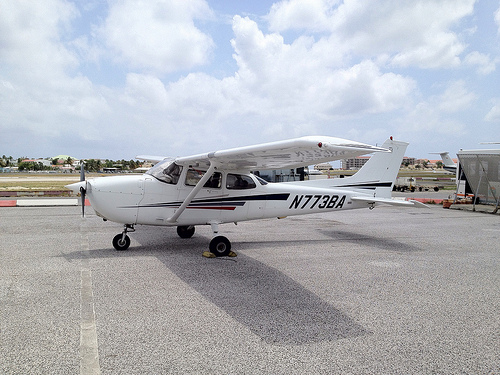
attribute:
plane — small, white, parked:
[62, 131, 432, 256]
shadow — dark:
[60, 223, 428, 344]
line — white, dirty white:
[77, 213, 105, 374]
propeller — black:
[79, 160, 87, 215]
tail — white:
[353, 138, 411, 192]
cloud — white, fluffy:
[106, 0, 216, 71]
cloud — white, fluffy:
[271, 0, 474, 69]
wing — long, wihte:
[176, 134, 394, 171]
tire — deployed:
[110, 233, 130, 252]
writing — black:
[290, 193, 348, 209]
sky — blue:
[56, 0, 500, 128]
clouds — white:
[0, 0, 499, 153]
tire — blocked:
[211, 235, 232, 257]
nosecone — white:
[60, 180, 86, 195]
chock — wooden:
[230, 249, 237, 256]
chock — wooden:
[203, 251, 217, 259]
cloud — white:
[228, 16, 417, 119]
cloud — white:
[1, 0, 86, 143]